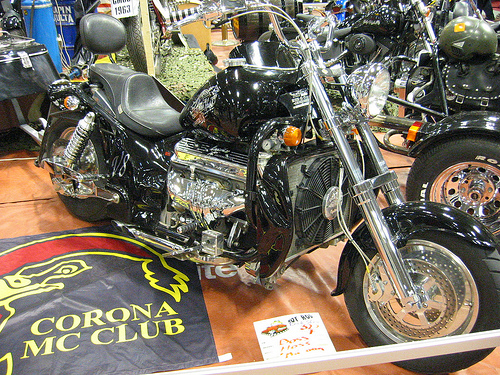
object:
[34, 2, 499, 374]
motorcycle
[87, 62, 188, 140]
seat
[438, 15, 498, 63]
helmet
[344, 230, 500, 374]
wheel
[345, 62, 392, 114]
headlight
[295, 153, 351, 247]
ventilation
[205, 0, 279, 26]
handelbars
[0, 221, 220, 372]
flag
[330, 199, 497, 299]
fender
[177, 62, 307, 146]
gas tank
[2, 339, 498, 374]
floor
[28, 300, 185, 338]
words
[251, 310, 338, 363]
paper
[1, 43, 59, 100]
bag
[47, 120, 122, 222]
wheel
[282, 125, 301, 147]
reflector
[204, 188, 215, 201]
silver